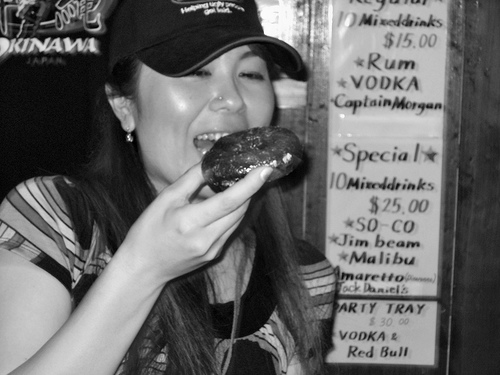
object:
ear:
[100, 78, 140, 134]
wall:
[0, 0, 500, 374]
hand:
[116, 160, 273, 283]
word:
[202, 7, 217, 17]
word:
[216, 7, 231, 14]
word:
[179, 1, 209, 15]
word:
[206, 0, 227, 8]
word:
[224, 0, 248, 15]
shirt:
[0, 170, 338, 374]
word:
[340, 138, 423, 175]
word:
[344, 175, 435, 195]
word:
[373, 234, 417, 249]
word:
[348, 249, 418, 267]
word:
[333, 268, 405, 281]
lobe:
[120, 119, 135, 132]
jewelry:
[216, 93, 225, 99]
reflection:
[157, 84, 189, 116]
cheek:
[136, 80, 202, 165]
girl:
[0, 0, 336, 374]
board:
[303, 0, 461, 370]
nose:
[208, 67, 247, 117]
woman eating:
[0, 0, 341, 374]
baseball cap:
[97, 2, 309, 84]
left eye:
[181, 66, 214, 78]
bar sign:
[320, 296, 442, 366]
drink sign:
[324, 138, 444, 301]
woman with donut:
[0, 0, 339, 374]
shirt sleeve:
[0, 173, 80, 296]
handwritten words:
[366, 46, 419, 71]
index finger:
[190, 163, 276, 223]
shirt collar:
[195, 235, 285, 339]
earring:
[124, 130, 136, 143]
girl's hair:
[80, 68, 328, 374]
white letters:
[175, 2, 255, 19]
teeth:
[213, 132, 221, 144]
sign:
[324, 0, 451, 141]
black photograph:
[0, 0, 499, 374]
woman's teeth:
[206, 133, 214, 142]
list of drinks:
[320, 1, 446, 369]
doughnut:
[199, 123, 311, 195]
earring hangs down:
[119, 127, 136, 143]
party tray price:
[363, 314, 413, 331]